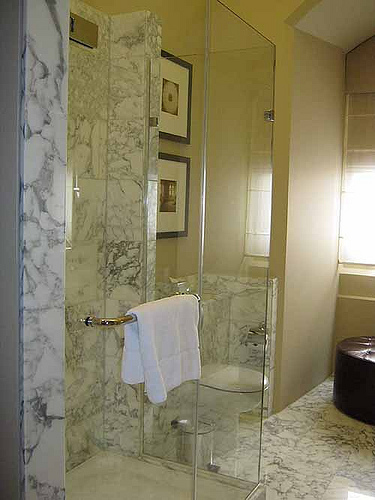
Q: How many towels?
A: 1.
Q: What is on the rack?
A: Towel.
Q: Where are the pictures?
A: On the wall.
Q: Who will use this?
A: People.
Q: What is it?
A: Restroom.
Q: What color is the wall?
A: Yellow.